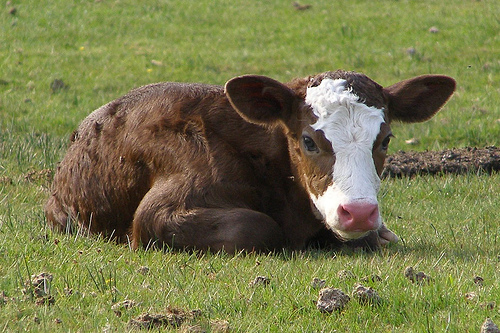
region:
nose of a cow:
[353, 210, 368, 222]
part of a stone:
[318, 277, 345, 303]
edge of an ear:
[247, 115, 280, 140]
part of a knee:
[224, 210, 284, 260]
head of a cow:
[307, 79, 363, 138]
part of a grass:
[417, 284, 444, 304]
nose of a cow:
[343, 195, 380, 242]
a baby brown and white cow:
[33, 40, 454, 273]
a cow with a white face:
[246, 31, 461, 256]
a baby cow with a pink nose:
[256, 32, 471, 244]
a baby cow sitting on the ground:
[39, 53, 464, 284]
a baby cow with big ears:
[195, 51, 472, 247]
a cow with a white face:
[261, 64, 456, 245]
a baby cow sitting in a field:
[23, 47, 468, 294]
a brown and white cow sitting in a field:
[43, 50, 465, 286]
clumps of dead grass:
[166, 274, 406, 331]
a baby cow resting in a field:
[22, 48, 459, 266]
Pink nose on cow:
[317, 192, 394, 242]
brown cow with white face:
[218, 44, 439, 270]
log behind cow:
[395, 131, 497, 181]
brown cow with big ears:
[204, 48, 460, 161]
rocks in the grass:
[285, 260, 448, 326]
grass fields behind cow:
[47, 19, 206, 63]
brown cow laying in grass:
[22, 55, 446, 274]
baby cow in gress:
[42, 28, 431, 265]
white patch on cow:
[306, 88, 382, 183]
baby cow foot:
[347, 217, 423, 260]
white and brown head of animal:
[296, 67, 410, 202]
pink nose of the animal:
[326, 195, 388, 247]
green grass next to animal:
[412, 185, 475, 245]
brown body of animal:
[110, 86, 232, 190]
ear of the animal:
[216, 64, 296, 139]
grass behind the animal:
[74, 10, 172, 67]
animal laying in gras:
[78, 36, 440, 253]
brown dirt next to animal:
[433, 131, 488, 176]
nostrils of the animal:
[316, 199, 382, 241]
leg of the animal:
[135, 193, 280, 265]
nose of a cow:
[340, 212, 355, 225]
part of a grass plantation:
[74, 257, 113, 269]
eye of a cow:
[307, 139, 319, 145]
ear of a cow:
[253, 93, 259, 106]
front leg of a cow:
[238, 210, 244, 229]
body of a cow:
[181, 140, 197, 187]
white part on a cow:
[351, 160, 352, 172]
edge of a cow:
[312, 160, 319, 170]